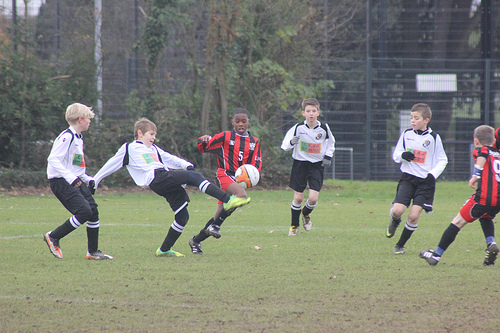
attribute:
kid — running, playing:
[120, 122, 249, 255]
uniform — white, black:
[111, 144, 226, 227]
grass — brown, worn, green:
[326, 277, 473, 321]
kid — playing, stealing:
[39, 111, 113, 250]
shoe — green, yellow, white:
[224, 191, 252, 214]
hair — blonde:
[66, 99, 94, 123]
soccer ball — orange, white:
[232, 161, 261, 190]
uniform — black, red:
[205, 132, 264, 193]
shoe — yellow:
[158, 247, 184, 260]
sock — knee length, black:
[85, 220, 102, 252]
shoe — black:
[418, 251, 436, 266]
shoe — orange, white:
[86, 250, 116, 262]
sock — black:
[49, 217, 81, 247]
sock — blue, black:
[432, 224, 460, 257]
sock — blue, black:
[480, 218, 496, 245]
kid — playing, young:
[201, 107, 261, 258]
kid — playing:
[284, 96, 335, 238]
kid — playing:
[393, 100, 447, 257]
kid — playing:
[424, 119, 499, 261]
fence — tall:
[5, 7, 499, 186]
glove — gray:
[290, 139, 304, 145]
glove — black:
[402, 153, 415, 163]